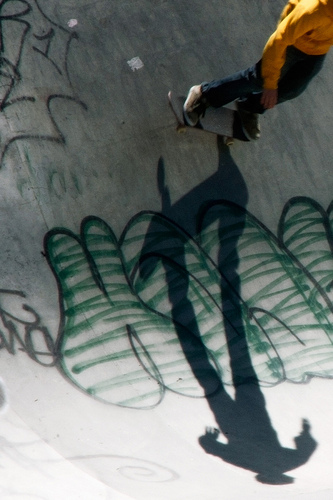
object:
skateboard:
[167, 90, 260, 142]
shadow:
[138, 134, 318, 486]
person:
[182, 0, 332, 140]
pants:
[200, 44, 327, 111]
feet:
[183, 82, 206, 128]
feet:
[235, 97, 261, 141]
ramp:
[1, 0, 332, 498]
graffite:
[31, 26, 63, 78]